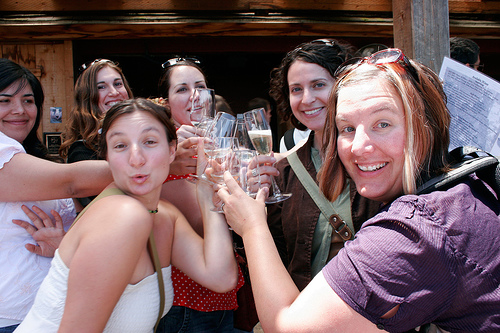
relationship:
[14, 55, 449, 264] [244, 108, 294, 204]
girls have glass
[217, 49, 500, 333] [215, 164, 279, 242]
girls has hand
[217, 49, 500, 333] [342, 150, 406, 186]
girls has a smile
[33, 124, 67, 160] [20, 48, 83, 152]
placque on wall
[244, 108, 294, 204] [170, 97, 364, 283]
glass are being toasted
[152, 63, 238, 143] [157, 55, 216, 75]
woman has sunglasses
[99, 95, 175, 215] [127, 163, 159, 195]
woman making kiss lips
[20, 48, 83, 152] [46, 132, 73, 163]
wall has a sign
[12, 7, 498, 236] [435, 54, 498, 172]
restaurant has menu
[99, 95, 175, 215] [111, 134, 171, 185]
woman making a kissing face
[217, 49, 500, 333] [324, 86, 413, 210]
girls has a face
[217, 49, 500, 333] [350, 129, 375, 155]
girls has a nose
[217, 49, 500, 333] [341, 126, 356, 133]
girls has eye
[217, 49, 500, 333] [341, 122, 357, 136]
girls has eye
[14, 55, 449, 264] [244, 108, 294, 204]
people hold glass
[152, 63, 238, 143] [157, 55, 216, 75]
person has eyeglasses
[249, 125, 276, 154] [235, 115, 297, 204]
champagne in a glass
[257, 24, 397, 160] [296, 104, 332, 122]
person has teeth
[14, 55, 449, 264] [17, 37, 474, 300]
women are at a party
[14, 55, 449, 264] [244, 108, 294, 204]
women are holding up glass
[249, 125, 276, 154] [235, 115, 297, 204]
champagne iin glass